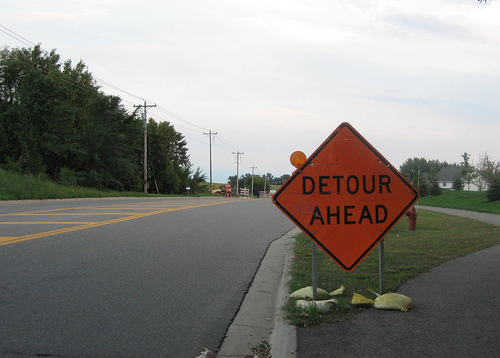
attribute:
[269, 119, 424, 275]
detour sign — orange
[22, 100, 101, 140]
leaves — green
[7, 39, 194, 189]
trees — many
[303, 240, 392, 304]
posts — gray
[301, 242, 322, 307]
post — gray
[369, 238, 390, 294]
post — gray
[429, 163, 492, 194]
house — white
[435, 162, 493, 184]
roof — gray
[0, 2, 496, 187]
sky — overcast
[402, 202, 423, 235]
hydrant — red, fire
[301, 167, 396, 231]
lettering — black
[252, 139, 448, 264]
sign — black, orange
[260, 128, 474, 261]
sign — orange, black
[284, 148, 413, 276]
sign — black, orange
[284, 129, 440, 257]
sign — orange, black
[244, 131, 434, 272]
sign — black, orange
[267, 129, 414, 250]
sign — orange, black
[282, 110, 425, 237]
sign — black, orange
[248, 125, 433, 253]
sign — orange, black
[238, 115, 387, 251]
sign — black, orange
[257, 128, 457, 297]
sign — orange, black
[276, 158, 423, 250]
sign — black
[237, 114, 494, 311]
sign — orange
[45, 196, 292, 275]
lines — yellow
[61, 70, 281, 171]
wires — attached, electrical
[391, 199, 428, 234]
hydrant — red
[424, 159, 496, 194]
house — distant, white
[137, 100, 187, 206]
pole — wooden, brown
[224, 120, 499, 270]
sign — black, orange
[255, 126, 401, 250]
sign — orange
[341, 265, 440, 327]
bag — sand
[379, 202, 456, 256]
hydrant — red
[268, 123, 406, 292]
sign — detour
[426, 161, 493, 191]
house — white, grey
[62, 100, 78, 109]
leaves — green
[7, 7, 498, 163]
sky — light blue, white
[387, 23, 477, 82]
clouds — streaky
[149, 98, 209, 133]
wires — electrical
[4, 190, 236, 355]
street — dark, paved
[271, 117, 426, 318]
sign — construction, barrier, orange, traffic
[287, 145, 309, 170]
light — orange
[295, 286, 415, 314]
bags — weighted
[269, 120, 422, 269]
sign — orange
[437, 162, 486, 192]
house — white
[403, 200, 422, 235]
fire-hydrant — red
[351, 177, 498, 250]
grass — shape of triangle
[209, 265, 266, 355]
border — gray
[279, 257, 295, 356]
curb — grassy